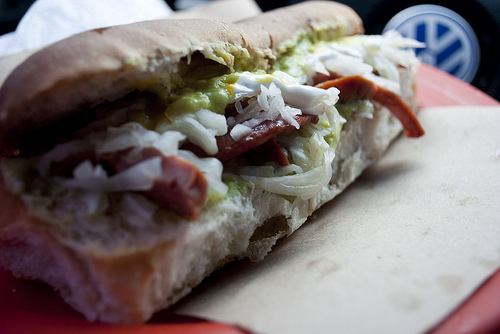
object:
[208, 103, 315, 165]
meat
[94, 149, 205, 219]
meat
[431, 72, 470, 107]
plate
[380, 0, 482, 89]
logo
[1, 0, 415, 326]
bread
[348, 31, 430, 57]
veggies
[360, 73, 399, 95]
veggies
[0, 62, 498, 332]
tray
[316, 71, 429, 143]
sticker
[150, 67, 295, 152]
spoonful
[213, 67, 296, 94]
cheese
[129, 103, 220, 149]
cheese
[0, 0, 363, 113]
top part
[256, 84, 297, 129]
onions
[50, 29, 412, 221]
veggies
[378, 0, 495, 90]
wheel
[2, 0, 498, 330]
napkin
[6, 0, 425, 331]
bun